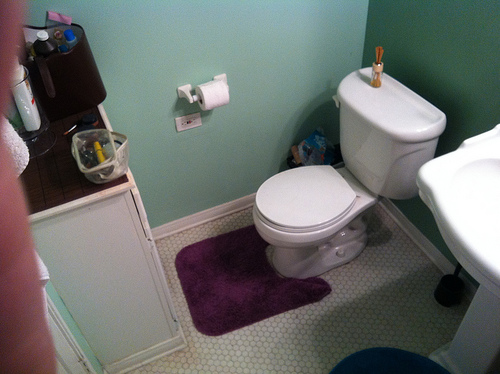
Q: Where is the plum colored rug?
A: In front of the toilet.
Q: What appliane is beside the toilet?
A: The sink.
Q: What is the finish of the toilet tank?
A: Porcelain.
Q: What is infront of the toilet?
A: A rug.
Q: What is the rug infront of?
A: A toilet.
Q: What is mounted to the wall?
A: The toilet paper roll holder.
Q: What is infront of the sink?
A: A mat.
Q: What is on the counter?
A: Beauty products.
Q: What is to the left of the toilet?
A: A trash.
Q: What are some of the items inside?
A: A bag.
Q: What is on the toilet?
A: Toilet brush.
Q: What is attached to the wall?
A: Paper holder.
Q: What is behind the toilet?
A: Bin.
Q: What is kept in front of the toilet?
A: Foot rug.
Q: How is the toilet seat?
A: Closed.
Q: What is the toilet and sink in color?
A: White.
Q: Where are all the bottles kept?
A: On shelf.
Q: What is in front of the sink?
A: Foot rug.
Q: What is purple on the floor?
A: Mat.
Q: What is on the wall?
A: Toliet paper.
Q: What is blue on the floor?
A: Mat.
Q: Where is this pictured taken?
A: Bathroom.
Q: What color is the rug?
A: Purple.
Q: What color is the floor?
A: White.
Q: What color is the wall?
A: Green.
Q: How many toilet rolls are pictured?
A: One.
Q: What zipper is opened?
A: Makeup Bag.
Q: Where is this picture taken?
A: In a bathroom.